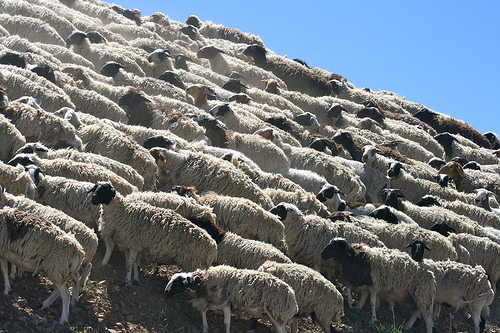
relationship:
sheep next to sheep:
[81, 117, 143, 186] [30, 52, 313, 288]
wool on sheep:
[225, 269, 329, 304] [171, 231, 336, 316]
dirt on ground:
[97, 286, 162, 318] [105, 290, 147, 326]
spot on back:
[8, 209, 39, 244] [2, 203, 89, 258]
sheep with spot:
[1, 204, 86, 324] [8, 209, 39, 244]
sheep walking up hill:
[12, 8, 494, 330] [8, 275, 181, 328]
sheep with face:
[290, 160, 348, 211] [291, 165, 350, 208]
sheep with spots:
[290, 160, 348, 211] [310, 181, 345, 211]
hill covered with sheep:
[23, 142, 468, 332] [19, 6, 484, 301]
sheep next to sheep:
[403, 241, 492, 328] [315, 234, 417, 324]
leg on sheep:
[356, 254, 383, 313] [307, 205, 454, 324]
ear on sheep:
[205, 83, 217, 98] [173, 49, 320, 144]